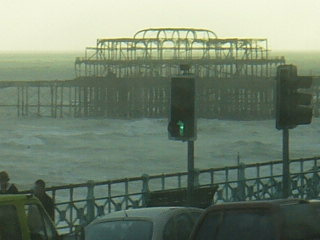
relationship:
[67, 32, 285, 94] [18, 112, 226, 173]
structure in ocean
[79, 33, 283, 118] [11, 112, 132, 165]
building toward water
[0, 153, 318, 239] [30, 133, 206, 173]
railing over ocean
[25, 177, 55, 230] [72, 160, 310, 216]
man between railing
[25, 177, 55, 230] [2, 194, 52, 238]
man between car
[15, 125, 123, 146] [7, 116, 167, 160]
waves on water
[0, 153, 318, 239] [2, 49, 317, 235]
railing overlooking ocean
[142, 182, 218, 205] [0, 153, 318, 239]
bench in front of railing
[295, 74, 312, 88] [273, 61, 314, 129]
cover on traffic light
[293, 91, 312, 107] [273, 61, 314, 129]
cover on traffic light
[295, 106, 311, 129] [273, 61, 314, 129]
cover on traffic light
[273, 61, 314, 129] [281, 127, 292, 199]
traffic light on pole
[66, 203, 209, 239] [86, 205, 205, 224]
car has roof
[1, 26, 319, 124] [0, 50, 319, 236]
structure frame in water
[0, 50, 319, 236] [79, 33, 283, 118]
water in front of building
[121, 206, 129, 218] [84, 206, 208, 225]
antenna on roof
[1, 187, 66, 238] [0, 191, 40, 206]
car has roof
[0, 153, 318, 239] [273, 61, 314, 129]
railing behind traffic light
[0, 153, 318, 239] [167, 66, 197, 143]
railing behind light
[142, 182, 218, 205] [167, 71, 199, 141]
bench beneath traffic light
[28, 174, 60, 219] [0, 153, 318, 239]
pedestrian standing next to railing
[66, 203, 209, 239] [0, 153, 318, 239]
car parked next to railing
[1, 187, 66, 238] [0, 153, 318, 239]
car parked next to railing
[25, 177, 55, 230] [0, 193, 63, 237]
man near car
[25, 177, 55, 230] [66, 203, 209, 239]
man near car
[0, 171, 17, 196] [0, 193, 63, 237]
man near car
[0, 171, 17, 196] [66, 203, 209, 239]
man near car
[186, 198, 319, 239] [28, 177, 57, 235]
car near man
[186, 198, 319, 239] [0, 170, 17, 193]
car near man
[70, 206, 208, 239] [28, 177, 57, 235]
car near man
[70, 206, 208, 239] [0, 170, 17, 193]
car near man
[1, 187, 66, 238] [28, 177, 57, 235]
car near man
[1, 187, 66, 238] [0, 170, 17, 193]
car near man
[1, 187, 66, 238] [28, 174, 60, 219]
car near pedestrian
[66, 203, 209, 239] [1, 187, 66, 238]
car near car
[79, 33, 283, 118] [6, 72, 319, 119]
building on pier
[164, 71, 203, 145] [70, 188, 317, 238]
traffic light on roadway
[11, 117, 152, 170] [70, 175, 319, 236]
ocean next roadway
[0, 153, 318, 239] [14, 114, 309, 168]
railing along water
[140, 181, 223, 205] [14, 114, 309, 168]
bench overlooking water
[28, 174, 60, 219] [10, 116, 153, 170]
pedestrian along water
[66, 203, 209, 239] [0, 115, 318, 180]
car along water